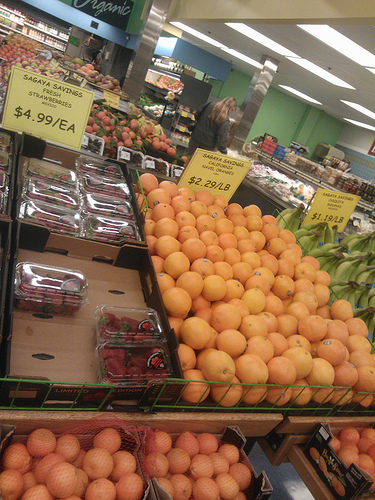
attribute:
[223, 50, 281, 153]
pillar — big, steel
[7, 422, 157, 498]
oranges — in a bag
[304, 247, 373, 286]
banana row — yellow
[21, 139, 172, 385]
strawberries — for sale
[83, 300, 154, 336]
strawberries — red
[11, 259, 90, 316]
strawberries — packed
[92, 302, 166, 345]
strawberries — packed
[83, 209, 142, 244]
strawberries — packed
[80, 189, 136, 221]
strawberries — packed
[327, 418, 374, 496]
oranges — grouped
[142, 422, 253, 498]
oranges — grouped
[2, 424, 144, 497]
oranges — grouped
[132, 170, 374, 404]
oranges — grouped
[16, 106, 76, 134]
price — written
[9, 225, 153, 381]
cardboard — plain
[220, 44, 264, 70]
light — big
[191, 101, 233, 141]
sweater — gray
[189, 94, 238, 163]
woman — shopping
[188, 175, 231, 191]
price — written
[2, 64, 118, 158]
price — written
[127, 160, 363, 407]
box — rectangle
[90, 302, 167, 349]
container — clear, plastic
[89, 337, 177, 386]
container — clear, plastic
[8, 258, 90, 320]
container — clear, plastic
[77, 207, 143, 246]
container — clear, plastic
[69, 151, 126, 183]
container — clear, plastic